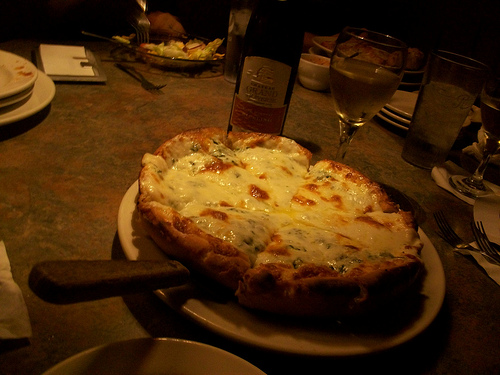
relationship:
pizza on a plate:
[141, 132, 425, 317] [120, 143, 446, 356]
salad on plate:
[127, 32, 220, 64] [120, 143, 446, 356]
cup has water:
[402, 42, 484, 169] [406, 80, 470, 171]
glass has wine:
[330, 20, 409, 165] [333, 30, 401, 120]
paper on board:
[40, 41, 102, 82] [34, 41, 103, 86]